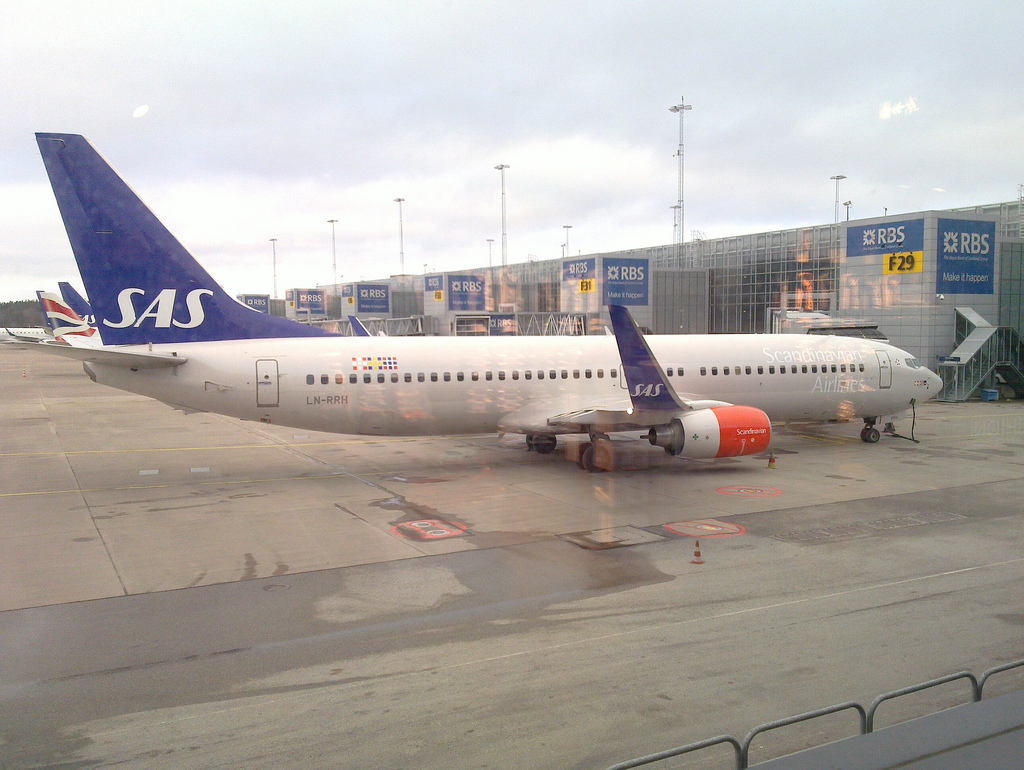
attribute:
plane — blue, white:
[114, 169, 959, 539]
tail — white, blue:
[23, 121, 238, 334]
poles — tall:
[484, 155, 495, 286]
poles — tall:
[821, 162, 848, 227]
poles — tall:
[392, 188, 400, 291]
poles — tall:
[265, 225, 276, 299]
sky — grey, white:
[170, 38, 984, 236]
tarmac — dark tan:
[49, 472, 408, 747]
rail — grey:
[650, 644, 994, 765]